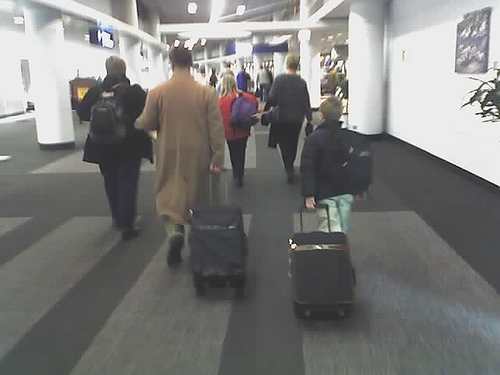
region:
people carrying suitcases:
[72, 0, 374, 320]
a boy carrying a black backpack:
[329, 120, 373, 193]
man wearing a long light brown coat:
[134, 67, 223, 227]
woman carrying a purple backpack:
[228, 87, 258, 129]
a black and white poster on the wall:
[452, 7, 490, 73]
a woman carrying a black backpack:
[91, 80, 131, 149]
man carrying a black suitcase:
[188, 163, 250, 296]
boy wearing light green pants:
[316, 193, 352, 235]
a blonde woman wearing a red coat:
[217, 71, 259, 138]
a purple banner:
[251, 40, 289, 52]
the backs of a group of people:
[86, 53, 374, 233]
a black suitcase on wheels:
[281, 194, 361, 330]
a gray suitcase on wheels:
[183, 165, 261, 294]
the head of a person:
[214, 72, 239, 93]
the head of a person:
[101, 53, 131, 82]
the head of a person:
[316, 95, 348, 122]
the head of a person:
[284, 55, 305, 77]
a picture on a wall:
[445, 11, 494, 76]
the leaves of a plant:
[465, 73, 498, 123]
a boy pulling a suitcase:
[280, 88, 379, 323]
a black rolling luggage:
[289, 203, 357, 323]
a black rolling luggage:
[187, 164, 242, 292]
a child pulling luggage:
[287, 96, 373, 324]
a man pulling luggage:
[135, 43, 247, 296]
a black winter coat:
[74, 75, 153, 163]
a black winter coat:
[301, 120, 356, 200]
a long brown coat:
[138, 74, 223, 221]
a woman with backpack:
[75, 53, 154, 236]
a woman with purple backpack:
[213, 70, 259, 187]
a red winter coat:
[217, 91, 261, 141]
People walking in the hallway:
[0, 0, 498, 374]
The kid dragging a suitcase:
[287, 97, 374, 324]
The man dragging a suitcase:
[136, 50, 251, 292]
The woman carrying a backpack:
[76, 58, 153, 240]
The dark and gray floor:
[0, 105, 498, 373]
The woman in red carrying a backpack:
[219, 72, 260, 187]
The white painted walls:
[0, 1, 497, 188]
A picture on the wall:
[454, 9, 491, 76]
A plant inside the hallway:
[462, 64, 499, 125]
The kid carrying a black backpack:
[301, 98, 378, 238]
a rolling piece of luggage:
[288, 205, 354, 320]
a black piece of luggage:
[189, 175, 249, 294]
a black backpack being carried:
[90, 88, 124, 140]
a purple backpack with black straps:
[230, 91, 255, 128]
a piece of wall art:
[453, 9, 487, 76]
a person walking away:
[263, 54, 315, 181]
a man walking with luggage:
[134, 45, 249, 292]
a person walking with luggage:
[289, 95, 371, 316]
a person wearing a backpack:
[79, 56, 148, 240]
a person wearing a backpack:
[217, 70, 261, 185]